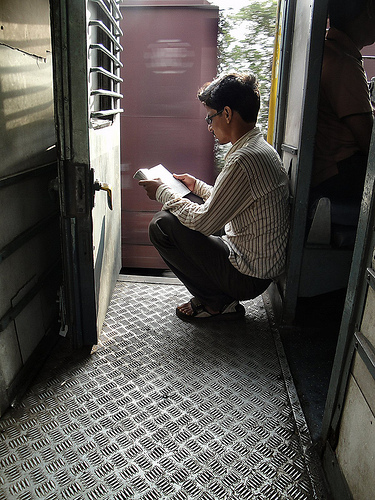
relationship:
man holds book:
[127, 57, 305, 335] [126, 156, 200, 204]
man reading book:
[127, 57, 305, 335] [126, 156, 200, 204]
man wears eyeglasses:
[127, 57, 305, 335] [198, 108, 224, 129]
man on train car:
[127, 57, 305, 335] [8, 4, 374, 496]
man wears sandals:
[127, 57, 305, 335] [163, 294, 254, 328]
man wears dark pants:
[127, 57, 305, 335] [138, 210, 270, 301]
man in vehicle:
[127, 57, 305, 335] [8, 4, 374, 496]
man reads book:
[127, 57, 305, 335] [126, 156, 200, 204]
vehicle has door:
[8, 4, 374, 496] [42, 0, 147, 354]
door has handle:
[42, 0, 147, 354] [90, 167, 120, 218]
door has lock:
[42, 0, 147, 354] [43, 152, 120, 219]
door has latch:
[42, 0, 147, 354] [46, 147, 98, 226]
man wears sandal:
[127, 57, 305, 335] [163, 294, 254, 328]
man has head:
[127, 57, 305, 335] [192, 59, 271, 154]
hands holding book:
[138, 170, 208, 209] [126, 156, 200, 204]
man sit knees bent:
[127, 57, 305, 335] [125, 205, 220, 285]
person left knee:
[127, 57, 305, 335] [141, 202, 186, 252]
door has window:
[42, 0, 147, 354] [85, 1, 126, 128]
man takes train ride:
[127, 57, 305, 335] [8, 4, 374, 496]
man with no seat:
[127, 57, 305, 335] [151, 283, 305, 346]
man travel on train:
[127, 57, 305, 335] [8, 4, 374, 496]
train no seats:
[8, 4, 374, 496] [27, 258, 316, 499]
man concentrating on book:
[127, 57, 305, 335] [126, 156, 200, 204]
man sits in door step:
[127, 57, 305, 335] [97, 265, 266, 335]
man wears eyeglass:
[127, 57, 305, 335] [198, 108, 224, 129]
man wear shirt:
[127, 57, 305, 335] [154, 126, 301, 284]